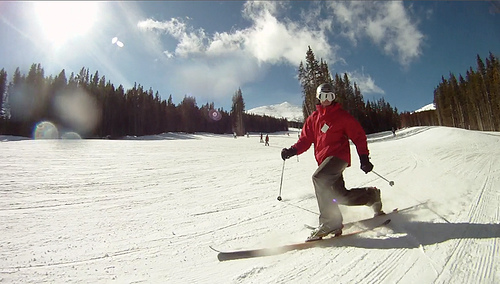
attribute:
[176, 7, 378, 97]
clouds — white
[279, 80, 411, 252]
skier — moving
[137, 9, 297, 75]
clouds sky — white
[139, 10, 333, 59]
clouds — white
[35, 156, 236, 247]
snow — white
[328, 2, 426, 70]
cloud — white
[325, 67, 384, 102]
cloud — white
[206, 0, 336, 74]
cloud — white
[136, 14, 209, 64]
cloud — white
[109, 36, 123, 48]
cloud — white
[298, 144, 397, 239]
pants — brown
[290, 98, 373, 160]
jacket — red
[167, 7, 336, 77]
cloud — white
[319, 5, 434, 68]
cloud — white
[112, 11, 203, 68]
cloud — white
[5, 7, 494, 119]
sky — blue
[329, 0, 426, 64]
cloud — white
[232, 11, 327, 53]
cloud — white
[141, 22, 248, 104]
cloud — white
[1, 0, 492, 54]
sky — blue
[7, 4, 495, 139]
sky — blue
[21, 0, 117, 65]
sun — winter sun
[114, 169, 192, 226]
snow — white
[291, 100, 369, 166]
coat — red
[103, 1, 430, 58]
clouds — white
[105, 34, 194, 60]
clouds — white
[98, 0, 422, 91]
clouds — white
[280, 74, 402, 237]
person — skiing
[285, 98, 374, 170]
coat — skiing coat, red, puffy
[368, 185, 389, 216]
boot — white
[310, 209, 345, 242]
boot — white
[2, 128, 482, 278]
snow — white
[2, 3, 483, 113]
sky — blue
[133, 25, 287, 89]
clouds — white